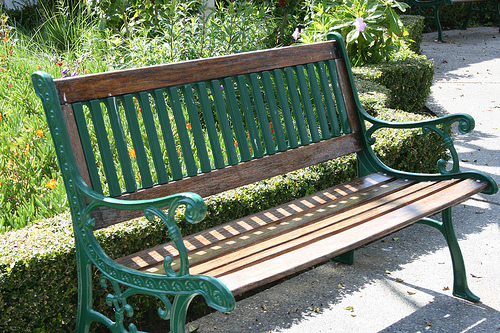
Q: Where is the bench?
A: On the sidewalk.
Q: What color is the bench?
A: Green and brown.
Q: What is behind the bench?
A: Plants.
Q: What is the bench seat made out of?
A: Wood.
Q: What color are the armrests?
A: Green.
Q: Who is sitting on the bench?
A: No one.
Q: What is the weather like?
A: Sunny.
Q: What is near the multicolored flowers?
A: Green bushes.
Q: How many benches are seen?
A: One.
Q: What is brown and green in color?
A: Bench.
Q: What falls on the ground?
A: Shadow.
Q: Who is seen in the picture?
A: Nobody.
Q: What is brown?
A: The bench.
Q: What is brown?
A: The bench.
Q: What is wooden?
A: The bench.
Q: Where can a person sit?
A: Bench.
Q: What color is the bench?
A: Brown and green.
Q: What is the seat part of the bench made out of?
A: Wood.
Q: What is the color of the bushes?
A: Green.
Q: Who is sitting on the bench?
A: No one.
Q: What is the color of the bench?
A: Green and brown.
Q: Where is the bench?
A: In front of the bushes.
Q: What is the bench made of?
A: Wood and metal.